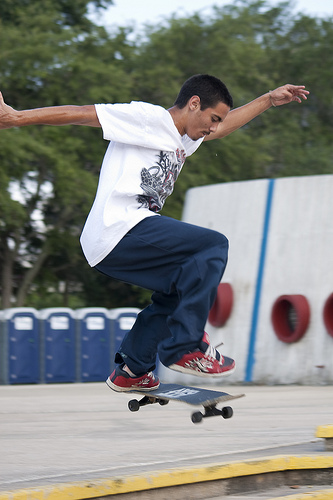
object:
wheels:
[191, 409, 201, 425]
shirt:
[78, 101, 204, 269]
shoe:
[108, 362, 162, 391]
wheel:
[126, 399, 138, 412]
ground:
[0, 375, 333, 500]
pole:
[242, 178, 272, 385]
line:
[0, 452, 332, 500]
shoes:
[161, 332, 234, 380]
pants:
[90, 213, 228, 371]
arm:
[200, 92, 272, 141]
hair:
[173, 75, 234, 110]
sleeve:
[94, 100, 145, 143]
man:
[0, 73, 311, 392]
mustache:
[191, 127, 209, 146]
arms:
[17, 102, 164, 126]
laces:
[203, 342, 218, 360]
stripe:
[0, 450, 333, 500]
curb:
[156, 452, 332, 485]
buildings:
[0, 304, 42, 382]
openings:
[272, 298, 296, 344]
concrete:
[181, 174, 332, 382]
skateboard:
[118, 376, 246, 425]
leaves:
[29, 148, 76, 224]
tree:
[0, 0, 333, 314]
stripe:
[245, 179, 274, 384]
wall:
[182, 173, 333, 387]